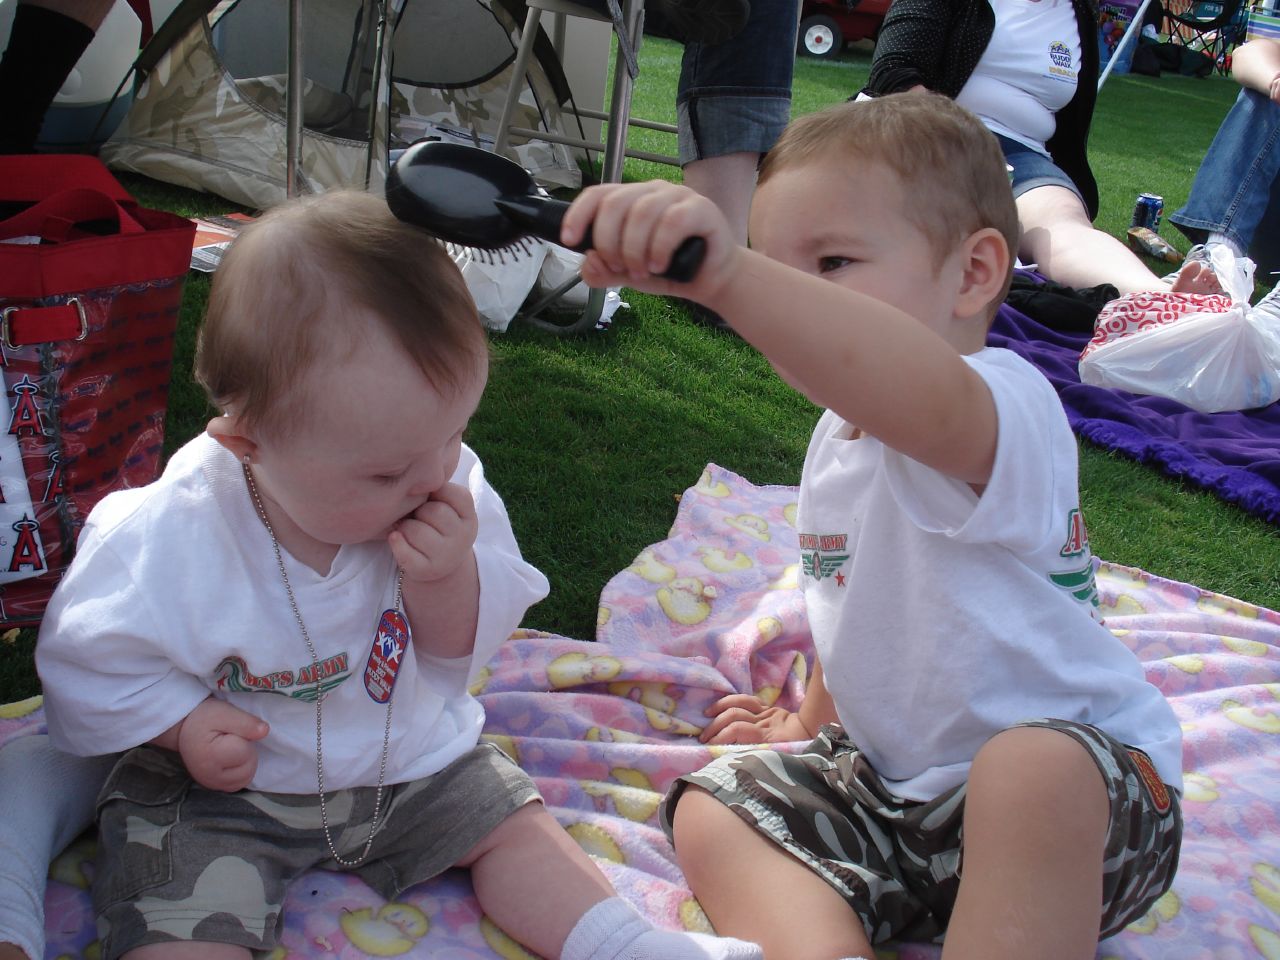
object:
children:
[25, 85, 1181, 960]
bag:
[1075, 243, 1278, 416]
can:
[1129, 193, 1164, 234]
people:
[842, 0, 1225, 295]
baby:
[28, 183, 758, 959]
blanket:
[0, 463, 1279, 960]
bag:
[0, 151, 200, 631]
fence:
[95, 0, 643, 340]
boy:
[558, 90, 1185, 960]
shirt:
[794, 347, 1185, 805]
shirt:
[31, 409, 549, 794]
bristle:
[503, 240, 531, 262]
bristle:
[482, 248, 494, 266]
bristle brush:
[385, 141, 709, 283]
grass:
[0, 40, 1280, 708]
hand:
[559, 176, 734, 301]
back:
[78, 404, 232, 549]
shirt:
[949, 0, 1081, 164]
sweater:
[844, 4, 1100, 224]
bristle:
[483, 248, 506, 265]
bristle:
[427, 234, 544, 265]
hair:
[193, 171, 485, 450]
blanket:
[986, 264, 1279, 528]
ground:
[0, 0, 1277, 960]